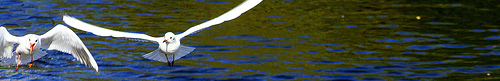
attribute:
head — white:
[20, 34, 45, 44]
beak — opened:
[12, 41, 47, 54]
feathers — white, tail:
[153, 49, 206, 62]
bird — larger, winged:
[80, 9, 260, 71]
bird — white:
[10, 27, 68, 74]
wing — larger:
[66, 9, 122, 46]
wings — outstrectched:
[57, 17, 258, 51]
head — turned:
[148, 25, 214, 70]